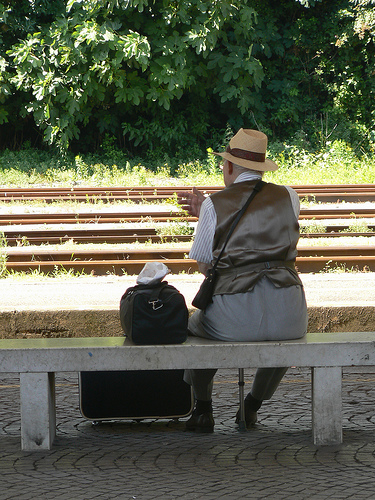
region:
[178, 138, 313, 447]
an old person sitting on a bench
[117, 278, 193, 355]
a black duffle bag on a bench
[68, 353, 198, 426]
a black suit case on the ground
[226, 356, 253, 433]
a cane with a rubber tip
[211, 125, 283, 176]
a tan hat on an old person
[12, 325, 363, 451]
a white granite bench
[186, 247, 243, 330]
a black shoulder bag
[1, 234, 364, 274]
a metal rail road track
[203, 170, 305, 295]
a shiny vest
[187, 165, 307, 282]
a white striped dress shirt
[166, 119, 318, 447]
an old man sitting on a bench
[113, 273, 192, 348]
a black duffle bag on bench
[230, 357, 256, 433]
a silver cane with a grey rubber tip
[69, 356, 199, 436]
a black suitcase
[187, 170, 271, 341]
a black shoulder bag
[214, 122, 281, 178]
a hat on a persons head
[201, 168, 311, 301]
a vest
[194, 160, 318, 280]
a striped shirt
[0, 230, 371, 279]
a train track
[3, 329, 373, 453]
a concrete bench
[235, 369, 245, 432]
the bottom of a cane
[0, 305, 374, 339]
bare brown dirt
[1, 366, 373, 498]
a concrete walkway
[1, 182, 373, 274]
rusted colored train tracks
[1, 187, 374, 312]
light shining on the ground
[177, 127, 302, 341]
a man wearing a hat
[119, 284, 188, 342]
a black bag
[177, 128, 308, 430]
a man wearing glasses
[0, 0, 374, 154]
trees growing in the background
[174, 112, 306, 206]
the man is wearing a hat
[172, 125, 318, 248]
the man has his hand out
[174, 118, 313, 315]
the man is wearing a bag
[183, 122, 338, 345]
the man is sitting on a bench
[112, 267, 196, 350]
the man has luggage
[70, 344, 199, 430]
the man's briefcase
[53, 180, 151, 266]
there is train tracks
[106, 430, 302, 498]
the ground is made of stone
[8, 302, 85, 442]
part of the bench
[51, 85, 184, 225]
green leaves in a background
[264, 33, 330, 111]
green leaves in a backgroundgreen leaves in a background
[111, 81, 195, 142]
green leaves in a background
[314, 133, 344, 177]
green leaves in a background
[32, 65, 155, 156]
green leaves in a background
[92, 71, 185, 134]
green leaves in a background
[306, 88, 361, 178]
green leaves in a background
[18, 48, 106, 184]
green leaves in a background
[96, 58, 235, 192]
green leaves in a background